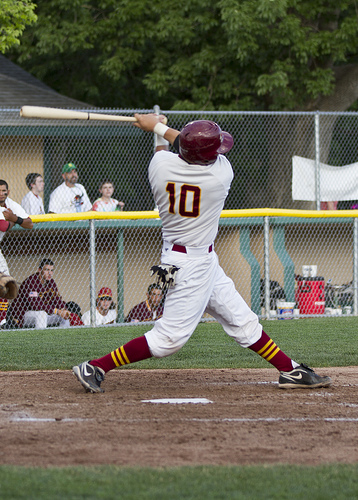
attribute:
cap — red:
[97, 288, 116, 298]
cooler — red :
[295, 272, 327, 320]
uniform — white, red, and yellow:
[88, 148, 300, 374]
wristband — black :
[171, 129, 181, 152]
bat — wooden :
[20, 105, 167, 121]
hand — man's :
[133, 112, 159, 128]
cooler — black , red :
[294, 273, 326, 314]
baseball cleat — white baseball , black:
[276, 365, 331, 388]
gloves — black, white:
[149, 262, 178, 286]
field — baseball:
[2, 280, 357, 497]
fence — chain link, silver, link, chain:
[1, 103, 356, 332]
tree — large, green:
[146, 5, 300, 91]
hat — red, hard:
[173, 118, 244, 163]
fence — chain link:
[2, 108, 357, 261]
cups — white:
[297, 262, 320, 276]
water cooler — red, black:
[295, 273, 325, 314]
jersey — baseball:
[146, 150, 234, 249]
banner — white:
[289, 155, 356, 203]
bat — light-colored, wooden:
[17, 105, 138, 128]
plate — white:
[136, 390, 219, 408]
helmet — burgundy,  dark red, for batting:
[177, 118, 233, 165]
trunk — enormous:
[245, 85, 351, 200]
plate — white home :
[142, 391, 209, 409]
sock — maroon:
[88, 335, 151, 372]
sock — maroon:
[247, 329, 293, 371]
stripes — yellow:
[109, 346, 132, 367]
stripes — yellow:
[257, 337, 282, 361]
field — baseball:
[6, 306, 350, 498]